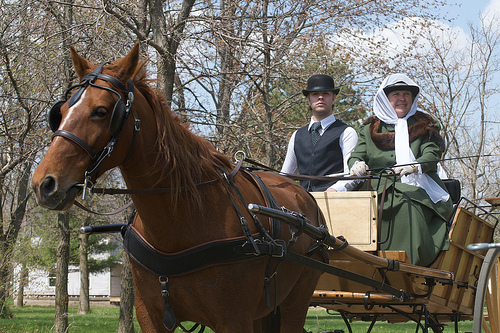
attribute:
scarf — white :
[371, 70, 451, 202]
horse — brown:
[29, 43, 329, 331]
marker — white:
[53, 80, 85, 143]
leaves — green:
[278, 52, 362, 125]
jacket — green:
[365, 126, 445, 266]